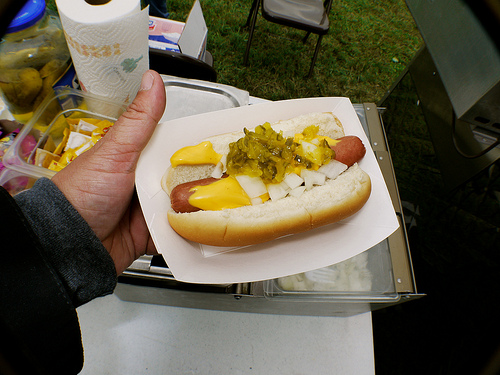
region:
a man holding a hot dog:
[21, 75, 401, 285]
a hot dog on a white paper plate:
[141, 94, 399, 280]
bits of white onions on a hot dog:
[236, 158, 351, 200]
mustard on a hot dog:
[167, 137, 214, 164]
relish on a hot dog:
[223, 124, 295, 181]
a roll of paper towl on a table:
[53, 0, 150, 120]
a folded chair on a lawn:
[245, 0, 342, 75]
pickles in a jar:
[0, 0, 88, 137]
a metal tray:
[154, 72, 251, 123]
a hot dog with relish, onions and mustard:
[165, 110, 374, 246]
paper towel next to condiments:
[54, 0, 149, 65]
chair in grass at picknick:
[247, 0, 323, 73]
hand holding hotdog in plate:
[46, 68, 163, 275]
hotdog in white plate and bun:
[165, 110, 371, 248]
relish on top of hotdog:
[236, 125, 298, 174]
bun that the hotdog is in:
[178, 210, 315, 227]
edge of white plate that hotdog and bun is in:
[171, 257, 231, 284]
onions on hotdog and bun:
[306, 168, 323, 185]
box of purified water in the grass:
[154, 15, 208, 45]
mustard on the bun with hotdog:
[171, 142, 218, 165]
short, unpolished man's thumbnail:
[130, 65, 165, 97]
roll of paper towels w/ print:
[49, 0, 152, 120]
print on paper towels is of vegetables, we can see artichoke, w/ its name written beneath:
[69, 52, 148, 111]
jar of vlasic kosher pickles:
[0, 0, 92, 126]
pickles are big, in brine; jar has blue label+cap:
[0, 0, 90, 135]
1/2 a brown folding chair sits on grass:
[240, 1, 345, 88]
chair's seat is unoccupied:
[258, 0, 336, 37]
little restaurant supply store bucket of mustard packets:
[0, 85, 135, 187]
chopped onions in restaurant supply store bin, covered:
[266, 227, 399, 298]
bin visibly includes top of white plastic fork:
[298, 265, 340, 289]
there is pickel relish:
[222, 117, 304, 182]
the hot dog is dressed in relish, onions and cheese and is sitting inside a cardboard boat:
[161, 106, 371, 236]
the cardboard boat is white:
[125, 93, 407, 285]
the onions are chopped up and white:
[236, 157, 336, 200]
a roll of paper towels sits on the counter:
[57, 0, 156, 111]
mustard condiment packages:
[14, 87, 129, 181]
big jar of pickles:
[2, 3, 87, 130]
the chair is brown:
[253, 3, 340, 79]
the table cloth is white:
[83, 301, 368, 374]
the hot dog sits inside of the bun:
[179, 108, 364, 245]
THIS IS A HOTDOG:
[153, 105, 377, 247]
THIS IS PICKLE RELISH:
[220, 115, 323, 178]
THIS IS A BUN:
[162, 107, 373, 252]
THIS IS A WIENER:
[168, 132, 368, 210]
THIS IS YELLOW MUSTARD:
[170, 140, 260, 215]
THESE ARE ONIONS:
[236, 159, 353, 204]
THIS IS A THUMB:
[70, 64, 178, 217]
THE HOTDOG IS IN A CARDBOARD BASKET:
[128, 93, 407, 304]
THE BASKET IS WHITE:
[130, 86, 411, 304]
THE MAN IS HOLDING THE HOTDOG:
[48, 64, 412, 329]